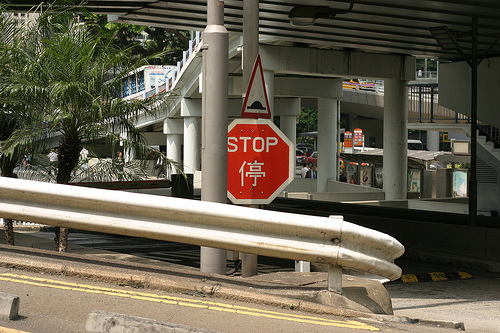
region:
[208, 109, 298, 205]
a red stop sign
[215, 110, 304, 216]
a sign with chinese character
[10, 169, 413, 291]
guard rails of a street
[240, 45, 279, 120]
a triangle sign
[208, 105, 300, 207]
a red plate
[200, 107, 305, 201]
a red traffic plate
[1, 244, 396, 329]
markings on the street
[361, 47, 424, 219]
stone pillars supporting bridge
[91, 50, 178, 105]
building on top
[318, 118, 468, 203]
a building on the street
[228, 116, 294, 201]
a white and red sign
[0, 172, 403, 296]
a curved metal railing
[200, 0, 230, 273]
a grey pole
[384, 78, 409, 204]
a large concrete cylinder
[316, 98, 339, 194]
a large concrete cylinder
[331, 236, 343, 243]
a bolt on a rail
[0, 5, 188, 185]
a small green tree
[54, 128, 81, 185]
trunk of a tree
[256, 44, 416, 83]
a concrete beam under a bridge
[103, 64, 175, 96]
a bus on a ramp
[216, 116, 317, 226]
sign is red and white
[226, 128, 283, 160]
white letters on sign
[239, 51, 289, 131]
sign is red and white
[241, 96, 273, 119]
black object on sign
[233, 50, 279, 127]
sign is triangular shaped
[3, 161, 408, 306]
ramp made of metal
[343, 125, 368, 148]
red objects on building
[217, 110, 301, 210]
sign is in shape of octagon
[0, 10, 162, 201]
tree under the bridge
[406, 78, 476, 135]
metal railing near the bridge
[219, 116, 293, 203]
A red stop sign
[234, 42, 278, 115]
A triangle speed bump sign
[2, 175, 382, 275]
A rail on the road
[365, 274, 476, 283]
A speed bump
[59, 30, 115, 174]
A palm tree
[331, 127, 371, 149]
two orange signs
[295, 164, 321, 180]
a man in a suit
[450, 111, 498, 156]
a set of stairs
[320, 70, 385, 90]
a yellow taxi with a red front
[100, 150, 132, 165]
a woman in black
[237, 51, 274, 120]
Triangular red, white and black sign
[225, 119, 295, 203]
Red and white octangular stop sign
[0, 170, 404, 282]
White metal guard rail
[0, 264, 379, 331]
Thin double yellow lines painted on the ground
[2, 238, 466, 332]
A concrete ramp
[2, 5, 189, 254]
Tree with spikey leaves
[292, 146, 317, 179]
Red car behind two people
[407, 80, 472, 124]
Black metal fence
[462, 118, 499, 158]
White staircase on the right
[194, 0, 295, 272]
Round white pole next to a red stop sign